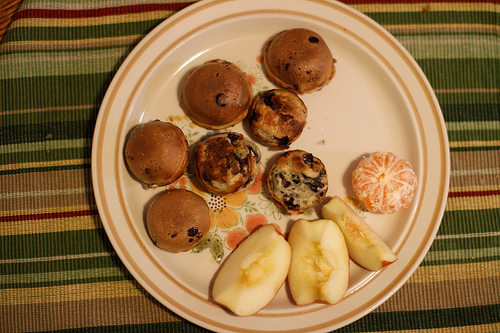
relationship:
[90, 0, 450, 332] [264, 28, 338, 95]
plate under pancake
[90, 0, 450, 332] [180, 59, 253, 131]
plate under pancake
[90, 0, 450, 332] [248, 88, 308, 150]
plate under pancake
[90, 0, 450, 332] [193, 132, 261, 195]
plate under pancake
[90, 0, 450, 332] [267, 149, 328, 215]
plate under pancake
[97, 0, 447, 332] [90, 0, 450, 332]
line on plate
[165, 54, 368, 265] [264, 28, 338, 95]
design under pancake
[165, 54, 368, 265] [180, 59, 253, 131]
design under pancake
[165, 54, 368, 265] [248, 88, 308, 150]
design under pancake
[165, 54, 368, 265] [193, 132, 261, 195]
design under pancake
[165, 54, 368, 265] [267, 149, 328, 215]
design under pancake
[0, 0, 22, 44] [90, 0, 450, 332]
table under plate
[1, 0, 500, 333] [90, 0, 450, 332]
tablecloth under plate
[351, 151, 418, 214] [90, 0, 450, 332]
orange on plate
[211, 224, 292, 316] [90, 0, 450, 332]
apple on plate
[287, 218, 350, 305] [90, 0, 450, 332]
apple on plate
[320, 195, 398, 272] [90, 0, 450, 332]
apple on plate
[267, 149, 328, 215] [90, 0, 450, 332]
pancake on plate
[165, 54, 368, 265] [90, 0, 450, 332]
design on plate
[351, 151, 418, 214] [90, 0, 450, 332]
orange on right of plate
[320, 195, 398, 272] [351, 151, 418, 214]
apple next to orange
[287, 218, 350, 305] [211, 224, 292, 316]
apple next to an apple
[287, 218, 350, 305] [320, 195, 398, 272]
apple next to an apple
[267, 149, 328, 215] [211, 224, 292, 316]
pancake next to an apple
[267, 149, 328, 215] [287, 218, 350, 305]
pancake next to an apple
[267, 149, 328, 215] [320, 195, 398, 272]
pancake next to an apple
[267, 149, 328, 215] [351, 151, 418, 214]
pancake next to an orange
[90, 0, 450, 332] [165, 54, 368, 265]
plate has a design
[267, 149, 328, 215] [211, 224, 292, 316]
pancake next to apple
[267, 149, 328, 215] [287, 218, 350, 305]
pancake next to apple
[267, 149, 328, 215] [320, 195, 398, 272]
pancake next to apple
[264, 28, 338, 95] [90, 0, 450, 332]
pancake on plate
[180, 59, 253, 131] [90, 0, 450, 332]
pancake on plate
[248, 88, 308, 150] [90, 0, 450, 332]
pancake on plate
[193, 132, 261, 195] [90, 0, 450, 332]
pancake on plate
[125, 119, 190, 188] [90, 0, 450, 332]
pancake on plate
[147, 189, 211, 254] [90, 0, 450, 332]
pancake on plate